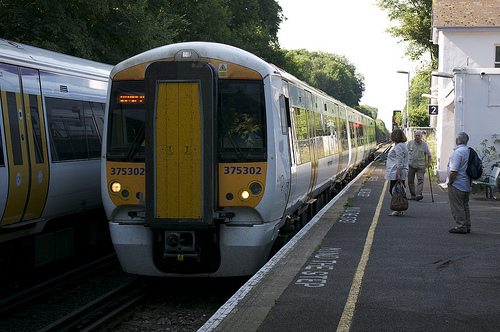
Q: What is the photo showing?
A: It is showing a station.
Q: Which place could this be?
A: It is a station.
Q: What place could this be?
A: It is a station.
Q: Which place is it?
A: It is a station.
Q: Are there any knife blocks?
A: No, there are no knife blocks.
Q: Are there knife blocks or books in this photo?
A: No, there are no knife blocks or books.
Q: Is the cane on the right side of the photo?
A: Yes, the cane is on the right of the image.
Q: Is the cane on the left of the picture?
A: No, the cane is on the right of the image.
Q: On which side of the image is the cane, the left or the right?
A: The cane is on the right of the image.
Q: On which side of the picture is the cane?
A: The cane is on the right of the image.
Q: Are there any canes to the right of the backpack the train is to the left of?
A: Yes, there is a cane to the right of the backpack.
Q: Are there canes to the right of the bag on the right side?
A: Yes, there is a cane to the right of the backpack.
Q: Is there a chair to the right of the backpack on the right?
A: No, there is a cane to the right of the backpack.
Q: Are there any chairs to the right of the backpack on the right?
A: No, there is a cane to the right of the backpack.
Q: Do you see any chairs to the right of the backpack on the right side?
A: No, there is a cane to the right of the backpack.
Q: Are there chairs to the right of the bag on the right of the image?
A: No, there is a cane to the right of the backpack.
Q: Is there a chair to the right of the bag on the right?
A: No, there is a cane to the right of the backpack.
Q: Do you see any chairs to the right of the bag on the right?
A: No, there is a cane to the right of the backpack.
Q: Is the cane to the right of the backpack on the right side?
A: Yes, the cane is to the right of the backpack.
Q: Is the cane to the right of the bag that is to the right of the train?
A: Yes, the cane is to the right of the backpack.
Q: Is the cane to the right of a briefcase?
A: No, the cane is to the right of the backpack.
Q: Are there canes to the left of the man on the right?
A: Yes, there is a cane to the left of the man.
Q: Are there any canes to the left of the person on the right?
A: Yes, there is a cane to the left of the man.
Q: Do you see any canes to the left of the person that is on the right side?
A: Yes, there is a cane to the left of the man.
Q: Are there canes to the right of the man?
A: No, the cane is to the left of the man.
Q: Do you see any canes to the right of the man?
A: No, the cane is to the left of the man.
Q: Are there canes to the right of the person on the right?
A: No, the cane is to the left of the man.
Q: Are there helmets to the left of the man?
A: No, there is a cane to the left of the man.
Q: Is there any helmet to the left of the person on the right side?
A: No, there is a cane to the left of the man.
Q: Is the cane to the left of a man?
A: Yes, the cane is to the left of a man.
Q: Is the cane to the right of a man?
A: No, the cane is to the left of a man.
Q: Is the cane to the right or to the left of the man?
A: The cane is to the left of the man.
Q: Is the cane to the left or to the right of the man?
A: The cane is to the left of the man.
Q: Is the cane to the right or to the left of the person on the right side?
A: The cane is to the left of the man.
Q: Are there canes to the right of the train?
A: Yes, there is a cane to the right of the train.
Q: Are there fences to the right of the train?
A: No, there is a cane to the right of the train.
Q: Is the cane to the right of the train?
A: Yes, the cane is to the right of the train.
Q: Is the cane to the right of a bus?
A: No, the cane is to the right of the train.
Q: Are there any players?
A: No, there are no players.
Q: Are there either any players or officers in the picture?
A: No, there are no players or officers.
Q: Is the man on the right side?
A: Yes, the man is on the right of the image.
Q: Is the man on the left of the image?
A: No, the man is on the right of the image.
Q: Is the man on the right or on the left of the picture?
A: The man is on the right of the image.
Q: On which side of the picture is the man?
A: The man is on the right of the image.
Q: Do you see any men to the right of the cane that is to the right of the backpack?
A: Yes, there is a man to the right of the cane.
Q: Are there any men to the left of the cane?
A: No, the man is to the right of the cane.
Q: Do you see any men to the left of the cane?
A: No, the man is to the right of the cane.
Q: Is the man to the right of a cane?
A: Yes, the man is to the right of a cane.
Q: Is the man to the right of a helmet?
A: No, the man is to the right of a cane.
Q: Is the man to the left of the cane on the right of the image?
A: No, the man is to the right of the cane.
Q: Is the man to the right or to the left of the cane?
A: The man is to the right of the cane.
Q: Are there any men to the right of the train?
A: Yes, there is a man to the right of the train.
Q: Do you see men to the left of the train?
A: No, the man is to the right of the train.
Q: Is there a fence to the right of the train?
A: No, there is a man to the right of the train.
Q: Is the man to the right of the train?
A: Yes, the man is to the right of the train.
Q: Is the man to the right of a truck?
A: No, the man is to the right of the train.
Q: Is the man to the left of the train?
A: No, the man is to the right of the train.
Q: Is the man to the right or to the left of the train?
A: The man is to the right of the train.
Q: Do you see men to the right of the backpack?
A: Yes, there is a man to the right of the backpack.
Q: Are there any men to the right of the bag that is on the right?
A: Yes, there is a man to the right of the backpack.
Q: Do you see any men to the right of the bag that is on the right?
A: Yes, there is a man to the right of the backpack.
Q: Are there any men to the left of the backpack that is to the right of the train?
A: No, the man is to the right of the backpack.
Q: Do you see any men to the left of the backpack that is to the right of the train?
A: No, the man is to the right of the backpack.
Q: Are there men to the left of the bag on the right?
A: No, the man is to the right of the backpack.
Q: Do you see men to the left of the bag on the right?
A: No, the man is to the right of the backpack.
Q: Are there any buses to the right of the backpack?
A: No, there is a man to the right of the backpack.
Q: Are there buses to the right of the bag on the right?
A: No, there is a man to the right of the backpack.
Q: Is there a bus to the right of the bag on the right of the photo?
A: No, there is a man to the right of the backpack.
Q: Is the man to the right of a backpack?
A: Yes, the man is to the right of a backpack.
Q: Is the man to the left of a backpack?
A: No, the man is to the right of a backpack.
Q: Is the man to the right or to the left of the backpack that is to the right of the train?
A: The man is to the right of the backpack.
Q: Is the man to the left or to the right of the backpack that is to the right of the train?
A: The man is to the right of the backpack.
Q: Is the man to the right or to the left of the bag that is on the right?
A: The man is to the right of the backpack.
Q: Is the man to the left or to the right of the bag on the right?
A: The man is to the right of the backpack.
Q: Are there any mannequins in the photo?
A: No, there are no mannequins.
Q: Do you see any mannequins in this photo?
A: No, there are no mannequins.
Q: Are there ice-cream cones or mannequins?
A: No, there are no mannequins or ice-cream cones.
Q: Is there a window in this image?
A: Yes, there is a window.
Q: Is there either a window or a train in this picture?
A: Yes, there is a window.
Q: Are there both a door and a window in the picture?
A: Yes, there are both a window and a door.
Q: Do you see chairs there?
A: No, there are no chairs.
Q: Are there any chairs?
A: No, there are no chairs.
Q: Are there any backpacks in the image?
A: Yes, there is a backpack.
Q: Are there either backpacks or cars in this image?
A: Yes, there is a backpack.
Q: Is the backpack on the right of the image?
A: Yes, the backpack is on the right of the image.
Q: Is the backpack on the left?
A: No, the backpack is on the right of the image.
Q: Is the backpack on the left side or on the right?
A: The backpack is on the right of the image.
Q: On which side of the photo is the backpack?
A: The backpack is on the right of the image.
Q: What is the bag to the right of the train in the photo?
A: The bag is a backpack.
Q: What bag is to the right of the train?
A: The bag is a backpack.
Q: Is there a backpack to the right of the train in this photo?
A: Yes, there is a backpack to the right of the train.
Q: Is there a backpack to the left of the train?
A: No, the backpack is to the right of the train.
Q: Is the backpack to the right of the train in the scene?
A: Yes, the backpack is to the right of the train.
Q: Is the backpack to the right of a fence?
A: No, the backpack is to the right of the train.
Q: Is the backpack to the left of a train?
A: No, the backpack is to the right of a train.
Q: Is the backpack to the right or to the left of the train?
A: The backpack is to the right of the train.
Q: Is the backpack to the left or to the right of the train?
A: The backpack is to the right of the train.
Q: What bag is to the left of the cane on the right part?
A: The bag is a backpack.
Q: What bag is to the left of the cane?
A: The bag is a backpack.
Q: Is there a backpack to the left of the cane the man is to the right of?
A: Yes, there is a backpack to the left of the cane.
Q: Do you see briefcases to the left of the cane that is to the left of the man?
A: No, there is a backpack to the left of the cane.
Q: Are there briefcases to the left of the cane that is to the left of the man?
A: No, there is a backpack to the left of the cane.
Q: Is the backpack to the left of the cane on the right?
A: Yes, the backpack is to the left of the cane.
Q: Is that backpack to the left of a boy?
A: No, the backpack is to the left of the cane.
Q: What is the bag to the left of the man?
A: The bag is a backpack.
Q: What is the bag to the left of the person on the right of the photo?
A: The bag is a backpack.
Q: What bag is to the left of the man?
A: The bag is a backpack.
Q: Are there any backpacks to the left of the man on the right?
A: Yes, there is a backpack to the left of the man.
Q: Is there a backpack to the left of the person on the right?
A: Yes, there is a backpack to the left of the man.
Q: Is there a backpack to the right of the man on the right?
A: No, the backpack is to the left of the man.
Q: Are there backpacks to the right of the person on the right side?
A: No, the backpack is to the left of the man.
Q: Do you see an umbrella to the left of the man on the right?
A: No, there is a backpack to the left of the man.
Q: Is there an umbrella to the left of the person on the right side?
A: No, there is a backpack to the left of the man.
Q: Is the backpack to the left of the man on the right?
A: Yes, the backpack is to the left of the man.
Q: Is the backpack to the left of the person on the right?
A: Yes, the backpack is to the left of the man.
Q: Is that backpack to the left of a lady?
A: No, the backpack is to the left of the man.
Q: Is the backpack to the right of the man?
A: No, the backpack is to the left of the man.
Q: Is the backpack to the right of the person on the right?
A: No, the backpack is to the left of the man.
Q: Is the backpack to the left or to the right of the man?
A: The backpack is to the left of the man.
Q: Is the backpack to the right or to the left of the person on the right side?
A: The backpack is to the left of the man.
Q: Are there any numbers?
A: Yes, there are numbers.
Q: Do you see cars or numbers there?
A: Yes, there are numbers.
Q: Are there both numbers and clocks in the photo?
A: No, there are numbers but no clocks.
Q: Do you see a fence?
A: No, there are no fences.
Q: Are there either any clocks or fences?
A: No, there are no fences or clocks.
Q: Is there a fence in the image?
A: No, there are no fences.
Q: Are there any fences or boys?
A: No, there are no fences or boys.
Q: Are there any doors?
A: Yes, there are doors.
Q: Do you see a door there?
A: Yes, there are doors.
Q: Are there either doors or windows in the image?
A: Yes, there are doors.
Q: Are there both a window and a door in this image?
A: Yes, there are both a door and a window.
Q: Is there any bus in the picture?
A: No, there are no buses.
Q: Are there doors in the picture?
A: Yes, there is a door.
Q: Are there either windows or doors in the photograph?
A: Yes, there is a door.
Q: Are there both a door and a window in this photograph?
A: Yes, there are both a door and a window.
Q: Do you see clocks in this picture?
A: No, there are no clocks.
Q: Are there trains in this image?
A: Yes, there is a train.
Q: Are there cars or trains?
A: Yes, there is a train.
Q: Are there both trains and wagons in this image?
A: No, there is a train but no wagons.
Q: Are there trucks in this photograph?
A: No, there are no trucks.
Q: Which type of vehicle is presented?
A: The vehicle is a train.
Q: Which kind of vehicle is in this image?
A: The vehicle is a train.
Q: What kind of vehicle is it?
A: The vehicle is a train.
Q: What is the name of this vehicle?
A: That is a train.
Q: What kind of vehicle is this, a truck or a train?
A: That is a train.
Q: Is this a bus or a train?
A: This is a train.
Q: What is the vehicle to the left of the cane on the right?
A: The vehicle is a train.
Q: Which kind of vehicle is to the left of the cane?
A: The vehicle is a train.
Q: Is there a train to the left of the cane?
A: Yes, there is a train to the left of the cane.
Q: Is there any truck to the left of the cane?
A: No, there is a train to the left of the cane.